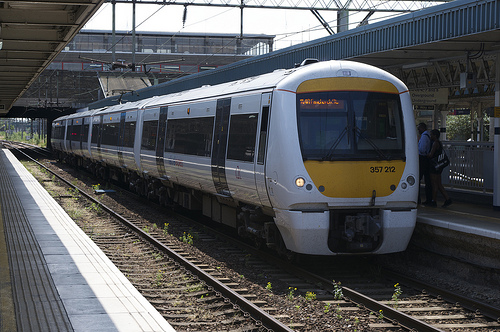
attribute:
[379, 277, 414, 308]
plant — small, green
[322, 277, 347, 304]
plant — small, green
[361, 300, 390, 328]
plant — small, green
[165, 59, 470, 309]
train — white, yellow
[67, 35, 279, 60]
overpass — blue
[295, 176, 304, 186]
light — lit up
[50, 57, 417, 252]
train — white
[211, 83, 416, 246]
train — modern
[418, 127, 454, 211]
person — waiting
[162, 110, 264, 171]
windows — large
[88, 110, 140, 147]
windows — large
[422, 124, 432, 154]
shirt — blue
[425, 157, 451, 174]
bag — black